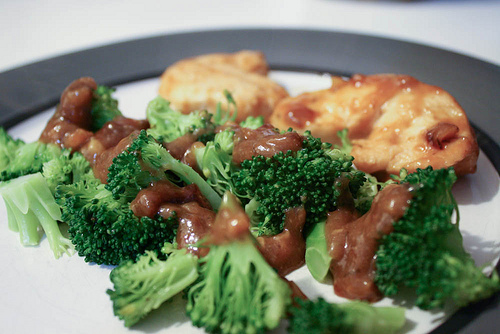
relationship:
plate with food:
[6, 26, 498, 333] [38, 54, 478, 332]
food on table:
[38, 54, 478, 332] [1, 0, 498, 332]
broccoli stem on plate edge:
[9, 174, 66, 253] [0, 62, 100, 319]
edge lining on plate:
[0, 26, 498, 163] [6, 26, 498, 333]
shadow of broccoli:
[455, 229, 497, 275] [304, 164, 499, 309]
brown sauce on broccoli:
[36, 77, 414, 305] [6, 82, 476, 332]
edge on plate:
[0, 26, 497, 130] [0, 15, 498, 173]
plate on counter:
[6, 26, 498, 333] [1, 3, 498, 50]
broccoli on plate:
[172, 236, 297, 332] [6, 26, 498, 333]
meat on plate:
[154, 47, 283, 129] [6, 26, 498, 333]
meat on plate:
[268, 68, 483, 185] [6, 26, 498, 333]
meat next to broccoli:
[268, 68, 483, 185] [103, 125, 397, 286]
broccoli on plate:
[103, 125, 397, 286] [6, 26, 498, 333]